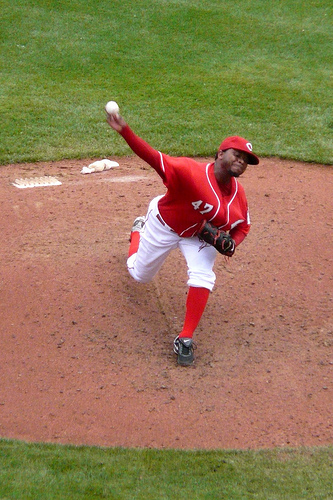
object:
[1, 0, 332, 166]
grass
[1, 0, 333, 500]
ground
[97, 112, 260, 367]
baseball player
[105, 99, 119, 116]
ball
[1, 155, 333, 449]
pitcher's mound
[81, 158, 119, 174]
bag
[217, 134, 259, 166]
baseball cap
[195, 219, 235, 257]
baseball glove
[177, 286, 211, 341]
sock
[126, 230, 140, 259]
sock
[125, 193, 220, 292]
pants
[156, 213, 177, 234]
cloth belt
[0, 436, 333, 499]
grass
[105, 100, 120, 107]
top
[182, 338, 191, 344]
logo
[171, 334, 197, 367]
shoe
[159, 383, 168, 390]
stone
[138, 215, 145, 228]
cleat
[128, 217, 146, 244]
foot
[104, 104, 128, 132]
hand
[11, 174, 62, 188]
base